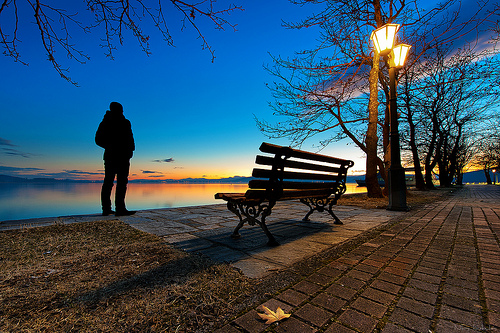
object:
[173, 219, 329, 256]
shadow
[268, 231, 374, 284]
ground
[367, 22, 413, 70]
lamps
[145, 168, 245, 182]
sunset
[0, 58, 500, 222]
horizon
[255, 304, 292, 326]
leaf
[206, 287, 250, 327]
ground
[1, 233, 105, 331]
ground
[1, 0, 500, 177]
sky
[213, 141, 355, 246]
bench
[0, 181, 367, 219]
water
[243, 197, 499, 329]
walkway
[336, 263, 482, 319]
bricks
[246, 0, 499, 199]
trees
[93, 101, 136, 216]
man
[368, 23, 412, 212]
pole light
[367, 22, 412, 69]
yellow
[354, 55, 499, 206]
bare